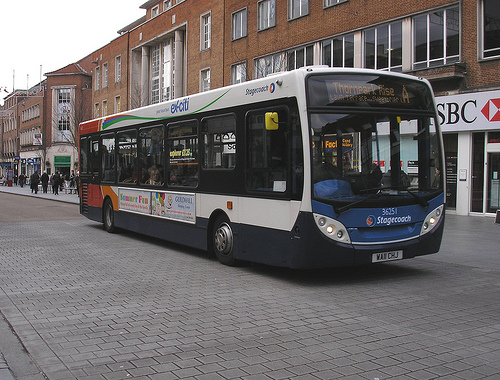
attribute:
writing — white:
[371, 208, 423, 238]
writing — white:
[367, 208, 414, 240]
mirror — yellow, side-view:
[264, 104, 289, 139]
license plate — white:
[367, 249, 408, 266]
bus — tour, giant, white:
[78, 62, 447, 272]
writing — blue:
[164, 97, 191, 117]